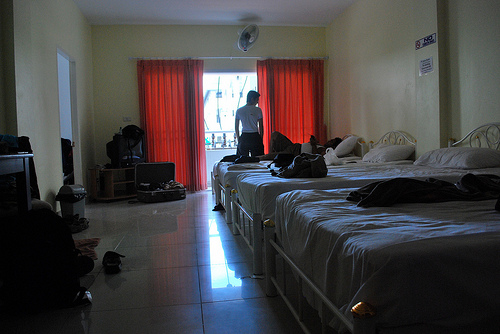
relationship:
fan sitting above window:
[235, 23, 259, 52] [202, 72, 257, 186]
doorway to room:
[58, 50, 77, 188] [58, 56, 71, 138]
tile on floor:
[119, 227, 193, 250] [92, 190, 281, 334]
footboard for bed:
[229, 186, 269, 284] [277, 188, 499, 333]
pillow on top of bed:
[360, 145, 415, 164] [277, 188, 499, 333]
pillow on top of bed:
[414, 148, 500, 169] [277, 188, 499, 333]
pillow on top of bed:
[335, 136, 356, 156] [214, 160, 284, 189]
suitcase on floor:
[137, 163, 185, 201] [92, 190, 281, 334]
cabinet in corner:
[91, 164, 136, 201] [90, 20, 94, 179]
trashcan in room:
[55, 184, 87, 219] [58, 56, 71, 138]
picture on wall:
[419, 57, 435, 74] [327, 1, 500, 147]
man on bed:
[240, 131, 343, 164] [214, 160, 284, 189]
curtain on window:
[136, 59, 202, 190] [202, 72, 257, 186]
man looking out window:
[233, 90, 265, 157] [202, 72, 257, 186]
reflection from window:
[205, 199, 236, 289] [202, 72, 257, 186]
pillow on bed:
[360, 145, 415, 164] [277, 188, 499, 333]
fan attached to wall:
[235, 23, 259, 52] [327, 1, 500, 147]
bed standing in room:
[277, 188, 499, 333] [2, 0, 483, 330]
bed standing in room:
[227, 120, 484, 280] [2, 0, 483, 330]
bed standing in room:
[217, 127, 418, 225] [2, 0, 483, 330]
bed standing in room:
[209, 130, 367, 211] [2, 0, 483, 330]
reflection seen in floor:
[205, 199, 236, 289] [56, 185, 322, 332]